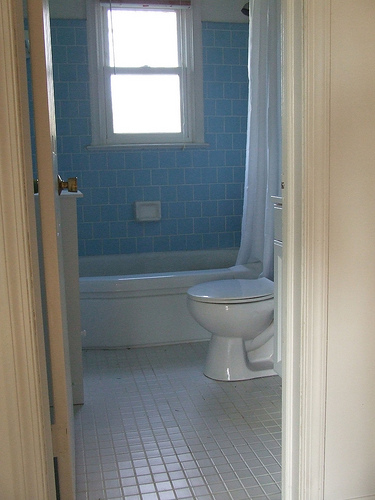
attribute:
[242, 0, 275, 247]
curtain — bright white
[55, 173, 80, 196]
door knob — dark colored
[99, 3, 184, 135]
window — white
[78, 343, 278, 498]
tiles — white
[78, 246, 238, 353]
bathtub — white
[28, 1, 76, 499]
door — brown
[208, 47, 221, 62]
tile — blue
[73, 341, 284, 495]
floor — white, bright white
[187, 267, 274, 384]
toilet — white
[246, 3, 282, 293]
curtain — open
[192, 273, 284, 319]
toilet seat — down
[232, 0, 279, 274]
shower curtain — white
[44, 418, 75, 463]
hinge — white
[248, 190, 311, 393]
vanity — bright white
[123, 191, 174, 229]
soap dish — white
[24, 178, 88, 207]
counter — white